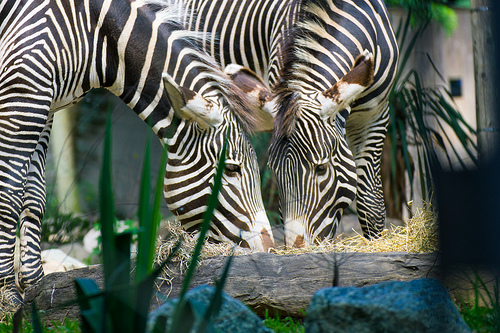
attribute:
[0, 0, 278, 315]
zebra — eating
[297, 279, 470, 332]
rock — blue, colorful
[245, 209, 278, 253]
nose — white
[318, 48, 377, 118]
ear — spotted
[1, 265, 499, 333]
grass — growing, tall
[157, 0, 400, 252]
zebra — eating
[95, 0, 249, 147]
neck — black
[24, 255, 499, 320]
rock — gray, long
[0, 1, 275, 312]
fur — white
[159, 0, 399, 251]
fur — black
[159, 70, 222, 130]
ear — black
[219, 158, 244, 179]
eye — black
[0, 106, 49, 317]
leg — black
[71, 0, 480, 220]
wall — concrete